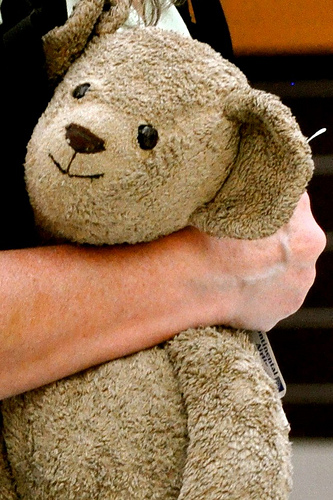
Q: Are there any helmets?
A: No, there are no helmets.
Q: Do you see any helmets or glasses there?
A: No, there are no helmets or glasses.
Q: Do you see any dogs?
A: No, there are no dogs.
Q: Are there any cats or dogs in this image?
A: No, there are no dogs or cats.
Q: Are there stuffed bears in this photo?
A: Yes, there is a stuffed bear.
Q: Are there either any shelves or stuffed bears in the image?
A: Yes, there is a stuffed bear.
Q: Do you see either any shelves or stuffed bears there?
A: Yes, there is a stuffed bear.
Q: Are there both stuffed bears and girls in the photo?
A: No, there is a stuffed bear but no girls.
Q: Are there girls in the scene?
A: No, there are no girls.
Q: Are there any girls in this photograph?
A: No, there are no girls.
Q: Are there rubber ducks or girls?
A: No, there are no girls or rubber ducks.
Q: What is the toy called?
A: The toy is a stuffed bear.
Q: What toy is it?
A: The toy is a stuffed bear.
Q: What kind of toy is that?
A: This is a stuffed bear.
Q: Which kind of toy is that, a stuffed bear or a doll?
A: This is a stuffed bear.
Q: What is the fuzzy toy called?
A: The toy is a stuffed bear.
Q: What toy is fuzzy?
A: The toy is a stuffed bear.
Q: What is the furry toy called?
A: The toy is a stuffed bear.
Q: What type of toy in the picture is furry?
A: The toy is a stuffed bear.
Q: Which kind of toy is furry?
A: The toy is a stuffed bear.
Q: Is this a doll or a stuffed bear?
A: This is a stuffed bear.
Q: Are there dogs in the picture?
A: No, there are no dogs.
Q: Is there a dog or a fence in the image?
A: No, there are no dogs or fences.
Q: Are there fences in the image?
A: No, there are no fences.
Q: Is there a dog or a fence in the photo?
A: No, there are no fences or dogs.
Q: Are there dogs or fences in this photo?
A: No, there are no fences or dogs.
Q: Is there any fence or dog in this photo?
A: No, there are no fences or dogs.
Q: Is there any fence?
A: No, there are no fences.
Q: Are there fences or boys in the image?
A: No, there are no fences or boys.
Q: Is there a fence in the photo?
A: No, there are no fences.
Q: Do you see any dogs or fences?
A: No, there are no fences or dogs.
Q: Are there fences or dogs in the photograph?
A: No, there are no fences or dogs.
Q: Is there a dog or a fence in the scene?
A: No, there are no fences or dogs.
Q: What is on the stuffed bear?
A: The tag is on the stuffed bear.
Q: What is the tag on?
A: The tag is on the stuffed bear.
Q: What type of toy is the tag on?
A: The tag is on the stuffed bear.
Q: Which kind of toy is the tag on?
A: The tag is on the stuffed bear.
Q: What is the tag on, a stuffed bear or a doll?
A: The tag is on a stuffed bear.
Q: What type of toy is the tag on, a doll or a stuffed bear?
A: The tag is on a stuffed bear.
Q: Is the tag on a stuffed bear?
A: Yes, the tag is on a stuffed bear.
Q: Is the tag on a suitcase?
A: No, the tag is on a stuffed bear.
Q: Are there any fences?
A: No, there are no fences.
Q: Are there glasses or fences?
A: No, there are no fences or glasses.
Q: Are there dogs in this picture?
A: No, there are no dogs.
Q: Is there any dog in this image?
A: No, there are no dogs.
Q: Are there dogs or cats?
A: No, there are no dogs or cats.